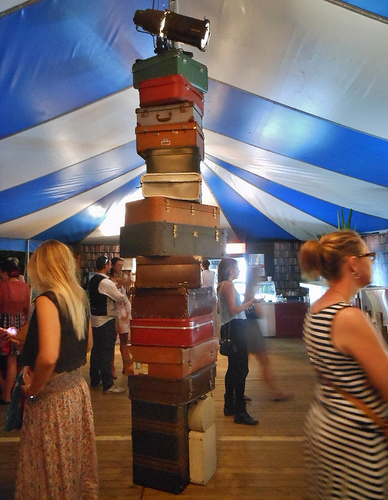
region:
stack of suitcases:
[102, 53, 199, 373]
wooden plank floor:
[237, 437, 286, 491]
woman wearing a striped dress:
[290, 313, 384, 467]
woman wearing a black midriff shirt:
[24, 283, 97, 374]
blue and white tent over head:
[4, 190, 105, 233]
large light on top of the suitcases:
[117, 5, 218, 57]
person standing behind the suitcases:
[212, 250, 271, 427]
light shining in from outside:
[234, 252, 250, 305]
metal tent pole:
[347, 2, 386, 28]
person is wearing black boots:
[219, 396, 260, 434]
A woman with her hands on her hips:
[11, 237, 96, 495]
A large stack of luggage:
[118, 48, 224, 493]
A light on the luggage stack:
[130, 8, 213, 63]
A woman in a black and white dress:
[294, 226, 385, 499]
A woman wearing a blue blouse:
[215, 257, 261, 423]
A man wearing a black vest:
[84, 254, 126, 395]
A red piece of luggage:
[130, 314, 218, 347]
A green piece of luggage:
[131, 51, 209, 91]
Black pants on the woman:
[222, 318, 255, 404]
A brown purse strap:
[310, 365, 385, 433]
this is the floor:
[230, 448, 263, 465]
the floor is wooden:
[234, 440, 282, 480]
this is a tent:
[257, 89, 310, 141]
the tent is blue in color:
[254, 111, 272, 128]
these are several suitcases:
[112, 51, 229, 486]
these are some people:
[18, 232, 367, 497]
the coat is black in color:
[92, 279, 98, 295]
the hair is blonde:
[43, 252, 62, 277]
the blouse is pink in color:
[221, 308, 224, 317]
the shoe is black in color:
[234, 405, 251, 419]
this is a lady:
[300, 213, 380, 492]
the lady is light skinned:
[345, 316, 374, 336]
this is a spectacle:
[358, 242, 385, 272]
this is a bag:
[218, 333, 240, 362]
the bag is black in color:
[222, 343, 232, 353]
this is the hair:
[46, 251, 74, 292]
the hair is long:
[65, 291, 81, 329]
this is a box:
[153, 52, 206, 78]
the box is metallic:
[177, 57, 195, 76]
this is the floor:
[230, 431, 269, 496]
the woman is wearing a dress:
[304, 300, 385, 499]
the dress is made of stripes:
[302, 300, 386, 495]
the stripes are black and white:
[302, 300, 384, 499]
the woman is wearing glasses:
[357, 248, 377, 262]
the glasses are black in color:
[357, 250, 376, 261]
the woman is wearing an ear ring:
[351, 271, 362, 279]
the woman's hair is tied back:
[301, 230, 365, 289]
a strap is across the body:
[309, 359, 386, 434]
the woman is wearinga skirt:
[16, 367, 105, 496]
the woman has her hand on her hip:
[18, 295, 60, 398]